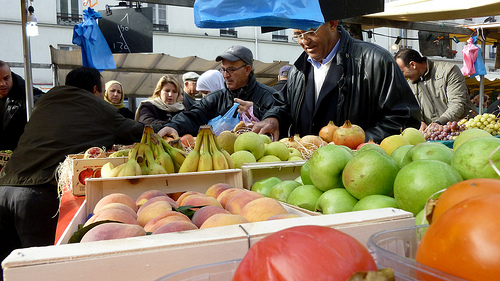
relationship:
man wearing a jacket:
[397, 47, 469, 132] [414, 59, 467, 119]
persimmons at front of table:
[222, 224, 388, 281] [55, 142, 491, 278]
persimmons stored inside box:
[222, 224, 388, 281] [159, 253, 407, 281]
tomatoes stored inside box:
[415, 177, 499, 281] [371, 178, 498, 280]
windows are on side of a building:
[57, 0, 81, 22] [1, 2, 499, 91]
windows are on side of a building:
[142, 0, 171, 33] [1, 2, 499, 91]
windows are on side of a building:
[222, 3, 236, 35] [1, 2, 499, 91]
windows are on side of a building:
[273, 3, 288, 39] [1, 2, 499, 91]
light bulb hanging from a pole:
[26, 6, 40, 38] [19, 0, 35, 125]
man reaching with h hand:
[253, 26, 416, 150] [249, 115, 286, 141]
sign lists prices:
[102, 10, 156, 54] [112, 12, 135, 55]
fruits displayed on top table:
[116, 124, 500, 232] [55, 142, 491, 278]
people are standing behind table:
[53, 23, 495, 135] [55, 142, 491, 278]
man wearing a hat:
[155, 43, 281, 138] [211, 42, 259, 66]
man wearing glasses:
[253, 26, 416, 150] [285, 26, 325, 43]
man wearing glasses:
[155, 43, 281, 138] [214, 65, 252, 75]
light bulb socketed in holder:
[26, 6, 40, 38] [27, 11, 38, 22]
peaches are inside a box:
[91, 191, 276, 229] [16, 175, 402, 280]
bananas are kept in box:
[110, 127, 231, 172] [94, 164, 244, 186]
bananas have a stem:
[110, 127, 231, 172] [142, 127, 158, 149]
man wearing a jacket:
[253, 26, 416, 150] [278, 47, 412, 128]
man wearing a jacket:
[155, 43, 281, 138] [164, 76, 274, 131]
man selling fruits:
[3, 61, 145, 248] [116, 124, 500, 232]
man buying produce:
[155, 43, 281, 138] [202, 104, 252, 134]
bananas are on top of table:
[110, 127, 231, 172] [55, 142, 491, 278]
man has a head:
[155, 43, 281, 138] [219, 61, 259, 94]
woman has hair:
[134, 74, 184, 132] [157, 75, 183, 87]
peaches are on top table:
[91, 191, 276, 229] [55, 142, 491, 278]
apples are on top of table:
[260, 142, 500, 212] [55, 142, 491, 278]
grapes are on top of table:
[424, 115, 462, 145] [55, 142, 491, 278]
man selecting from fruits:
[253, 26, 416, 150] [116, 124, 500, 232]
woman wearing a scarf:
[134, 74, 184, 132] [141, 102, 188, 110]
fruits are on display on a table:
[116, 124, 500, 232] [55, 142, 491, 278]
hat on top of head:
[211, 42, 259, 66] [219, 61, 259, 94]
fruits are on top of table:
[116, 124, 500, 232] [55, 142, 491, 278]